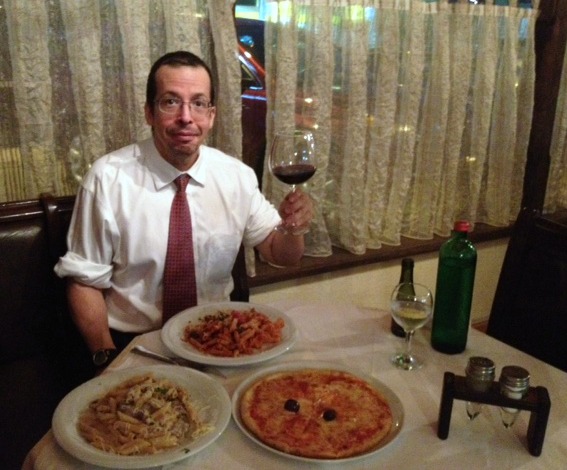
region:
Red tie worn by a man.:
[161, 173, 199, 318]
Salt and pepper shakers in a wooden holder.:
[434, 354, 553, 460]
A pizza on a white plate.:
[231, 361, 413, 461]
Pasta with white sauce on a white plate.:
[52, 363, 231, 466]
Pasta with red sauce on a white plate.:
[162, 301, 300, 365]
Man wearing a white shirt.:
[51, 48, 315, 367]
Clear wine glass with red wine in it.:
[265, 127, 319, 239]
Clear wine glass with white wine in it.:
[382, 278, 432, 378]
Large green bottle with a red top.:
[427, 217, 478, 359]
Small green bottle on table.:
[389, 253, 418, 336]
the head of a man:
[138, 52, 215, 161]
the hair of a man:
[163, 42, 201, 71]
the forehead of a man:
[168, 70, 203, 94]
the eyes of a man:
[160, 96, 209, 113]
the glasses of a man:
[153, 98, 215, 115]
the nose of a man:
[172, 104, 194, 127]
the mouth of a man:
[167, 128, 194, 142]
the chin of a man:
[161, 140, 203, 159]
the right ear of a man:
[131, 96, 162, 139]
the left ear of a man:
[207, 106, 221, 131]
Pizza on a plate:
[241, 365, 402, 460]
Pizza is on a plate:
[237, 366, 396, 461]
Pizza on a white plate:
[237, 358, 396, 459]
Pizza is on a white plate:
[241, 361, 397, 459]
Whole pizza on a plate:
[236, 362, 405, 468]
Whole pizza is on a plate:
[238, 360, 396, 461]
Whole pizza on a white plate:
[238, 363, 399, 463]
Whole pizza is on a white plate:
[239, 356, 396, 459]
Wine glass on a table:
[389, 273, 437, 375]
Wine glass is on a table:
[384, 272, 437, 374]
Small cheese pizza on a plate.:
[230, 355, 406, 460]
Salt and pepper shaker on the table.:
[422, 346, 562, 454]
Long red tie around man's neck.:
[162, 166, 199, 318]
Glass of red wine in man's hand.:
[265, 117, 316, 246]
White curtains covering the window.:
[257, 2, 543, 240]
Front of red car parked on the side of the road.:
[236, 7, 422, 190]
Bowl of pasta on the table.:
[56, 364, 214, 469]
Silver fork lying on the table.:
[129, 323, 229, 387]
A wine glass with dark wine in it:
[268, 129, 319, 238]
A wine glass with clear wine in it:
[391, 282, 432, 371]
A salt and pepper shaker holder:
[430, 355, 552, 461]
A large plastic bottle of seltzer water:
[429, 216, 477, 354]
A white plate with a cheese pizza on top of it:
[230, 358, 407, 468]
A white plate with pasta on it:
[49, 364, 233, 468]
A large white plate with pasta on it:
[157, 299, 301, 361]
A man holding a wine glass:
[59, 50, 314, 300]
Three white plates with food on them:
[51, 299, 410, 469]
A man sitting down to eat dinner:
[44, 47, 407, 469]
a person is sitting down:
[66, 52, 313, 345]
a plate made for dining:
[234, 343, 406, 466]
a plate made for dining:
[222, 351, 405, 464]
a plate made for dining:
[51, 351, 224, 458]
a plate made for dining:
[162, 286, 294, 364]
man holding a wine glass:
[55, 45, 368, 347]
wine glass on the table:
[369, 272, 437, 378]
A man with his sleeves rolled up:
[49, 45, 340, 377]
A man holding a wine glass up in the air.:
[46, 44, 346, 398]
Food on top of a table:
[28, 290, 459, 462]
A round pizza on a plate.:
[234, 356, 425, 454]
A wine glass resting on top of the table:
[385, 281, 431, 378]